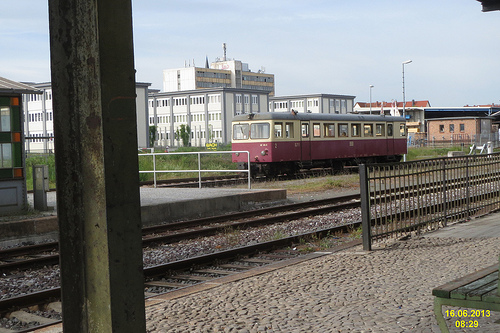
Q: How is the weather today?
A: It is clear.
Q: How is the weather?
A: It is clear.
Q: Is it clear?
A: Yes, it is clear.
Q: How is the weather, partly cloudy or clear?
A: It is clear.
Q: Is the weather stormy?
A: No, it is clear.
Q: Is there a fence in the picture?
A: Yes, there is a fence.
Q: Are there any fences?
A: Yes, there is a fence.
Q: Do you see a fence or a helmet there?
A: Yes, there is a fence.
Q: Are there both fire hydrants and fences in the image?
A: No, there is a fence but no fire hydrants.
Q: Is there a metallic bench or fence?
A: Yes, there is a metal fence.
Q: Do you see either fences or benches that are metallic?
A: Yes, the fence is metallic.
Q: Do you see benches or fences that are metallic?
A: Yes, the fence is metallic.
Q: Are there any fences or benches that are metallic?
A: Yes, the fence is metallic.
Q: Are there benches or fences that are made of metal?
A: Yes, the fence is made of metal.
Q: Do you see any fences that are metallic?
A: Yes, there is a metal fence.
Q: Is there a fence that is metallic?
A: Yes, there is a fence that is metallic.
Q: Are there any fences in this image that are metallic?
A: Yes, there is a fence that is metallic.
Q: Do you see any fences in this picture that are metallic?
A: Yes, there is a fence that is metallic.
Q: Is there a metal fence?
A: Yes, there is a fence that is made of metal.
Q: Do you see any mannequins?
A: No, there are no mannequins.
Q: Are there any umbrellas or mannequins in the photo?
A: No, there are no mannequins or umbrellas.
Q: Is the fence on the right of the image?
A: Yes, the fence is on the right of the image.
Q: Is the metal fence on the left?
A: No, the fence is on the right of the image.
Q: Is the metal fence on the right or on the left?
A: The fence is on the right of the image.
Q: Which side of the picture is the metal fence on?
A: The fence is on the right of the image.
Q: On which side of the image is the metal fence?
A: The fence is on the right of the image.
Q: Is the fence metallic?
A: Yes, the fence is metallic.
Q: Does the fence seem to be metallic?
A: Yes, the fence is metallic.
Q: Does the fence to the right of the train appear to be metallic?
A: Yes, the fence is metallic.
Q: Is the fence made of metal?
A: Yes, the fence is made of metal.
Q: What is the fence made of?
A: The fence is made of metal.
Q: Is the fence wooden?
A: No, the fence is metallic.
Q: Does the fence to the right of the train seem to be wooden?
A: No, the fence is metallic.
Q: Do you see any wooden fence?
A: No, there is a fence but it is metallic.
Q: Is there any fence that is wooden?
A: No, there is a fence but it is metallic.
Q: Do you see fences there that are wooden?
A: No, there is a fence but it is metallic.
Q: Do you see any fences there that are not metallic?
A: No, there is a fence but it is metallic.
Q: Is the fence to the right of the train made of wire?
A: No, the fence is made of metal.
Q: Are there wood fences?
A: No, there is a fence but it is made of metal.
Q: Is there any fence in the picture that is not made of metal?
A: No, there is a fence but it is made of metal.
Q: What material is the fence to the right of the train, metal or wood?
A: The fence is made of metal.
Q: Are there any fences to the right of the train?
A: Yes, there is a fence to the right of the train.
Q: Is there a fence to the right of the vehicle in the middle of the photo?
A: Yes, there is a fence to the right of the train.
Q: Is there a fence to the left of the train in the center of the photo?
A: No, the fence is to the right of the train.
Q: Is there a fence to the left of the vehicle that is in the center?
A: No, the fence is to the right of the train.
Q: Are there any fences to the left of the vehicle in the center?
A: No, the fence is to the right of the train.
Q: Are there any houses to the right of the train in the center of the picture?
A: No, there is a fence to the right of the train.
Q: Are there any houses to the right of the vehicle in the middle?
A: No, there is a fence to the right of the train.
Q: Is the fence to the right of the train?
A: Yes, the fence is to the right of the train.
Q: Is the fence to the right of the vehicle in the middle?
A: Yes, the fence is to the right of the train.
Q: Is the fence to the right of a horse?
A: No, the fence is to the right of the train.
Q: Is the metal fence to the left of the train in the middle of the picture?
A: No, the fence is to the right of the train.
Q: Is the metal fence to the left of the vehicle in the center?
A: No, the fence is to the right of the train.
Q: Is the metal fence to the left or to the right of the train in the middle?
A: The fence is to the right of the train.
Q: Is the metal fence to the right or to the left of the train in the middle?
A: The fence is to the right of the train.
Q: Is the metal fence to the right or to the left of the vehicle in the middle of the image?
A: The fence is to the right of the train.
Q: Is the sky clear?
A: Yes, the sky is clear.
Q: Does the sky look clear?
A: Yes, the sky is clear.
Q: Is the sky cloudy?
A: No, the sky is clear.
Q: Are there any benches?
A: Yes, there is a bench.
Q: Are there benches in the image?
A: Yes, there is a bench.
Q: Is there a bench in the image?
A: Yes, there is a bench.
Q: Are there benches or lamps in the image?
A: Yes, there is a bench.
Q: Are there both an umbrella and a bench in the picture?
A: No, there is a bench but no umbrellas.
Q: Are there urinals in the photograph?
A: No, there are no urinals.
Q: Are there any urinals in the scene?
A: No, there are no urinals.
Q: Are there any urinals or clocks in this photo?
A: No, there are no urinals or clocks.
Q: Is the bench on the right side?
A: Yes, the bench is on the right of the image.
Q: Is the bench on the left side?
A: No, the bench is on the right of the image.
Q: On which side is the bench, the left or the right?
A: The bench is on the right of the image.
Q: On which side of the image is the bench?
A: The bench is on the right of the image.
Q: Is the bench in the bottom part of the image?
A: Yes, the bench is in the bottom of the image.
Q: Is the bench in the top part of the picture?
A: No, the bench is in the bottom of the image.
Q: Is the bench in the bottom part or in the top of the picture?
A: The bench is in the bottom of the image.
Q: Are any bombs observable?
A: No, there are no bombs.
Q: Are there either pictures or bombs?
A: No, there are no bombs or pictures.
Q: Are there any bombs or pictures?
A: No, there are no bombs or pictures.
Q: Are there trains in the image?
A: Yes, there is a train.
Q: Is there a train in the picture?
A: Yes, there is a train.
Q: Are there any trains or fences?
A: Yes, there is a train.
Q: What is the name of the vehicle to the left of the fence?
A: The vehicle is a train.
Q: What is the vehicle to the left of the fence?
A: The vehicle is a train.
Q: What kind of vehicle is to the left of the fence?
A: The vehicle is a train.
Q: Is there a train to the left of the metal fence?
A: Yes, there is a train to the left of the fence.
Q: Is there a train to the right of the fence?
A: No, the train is to the left of the fence.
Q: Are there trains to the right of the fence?
A: No, the train is to the left of the fence.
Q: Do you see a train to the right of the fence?
A: No, the train is to the left of the fence.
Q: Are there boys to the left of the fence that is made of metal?
A: No, there is a train to the left of the fence.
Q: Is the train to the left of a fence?
A: Yes, the train is to the left of a fence.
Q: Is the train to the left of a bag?
A: No, the train is to the left of a fence.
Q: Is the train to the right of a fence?
A: No, the train is to the left of a fence.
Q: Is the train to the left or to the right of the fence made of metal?
A: The train is to the left of the fence.